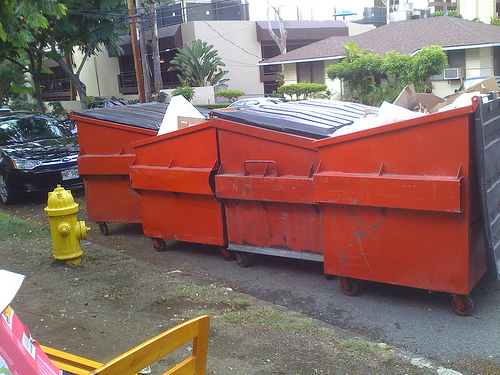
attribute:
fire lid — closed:
[58, 95, 166, 130]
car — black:
[2, 109, 90, 209]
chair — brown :
[30, 310, 237, 374]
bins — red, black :
[314, 93, 499, 315]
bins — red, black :
[211, 96, 383, 268]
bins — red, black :
[129, 121, 227, 251]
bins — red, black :
[72, 102, 228, 237]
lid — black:
[212, 77, 385, 157]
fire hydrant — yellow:
[37, 179, 97, 269]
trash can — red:
[310, 83, 493, 308]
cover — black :
[212, 86, 376, 138]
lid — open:
[475, 103, 498, 289]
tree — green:
[1, 0, 138, 111]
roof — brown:
[264, 17, 499, 63]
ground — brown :
[22, 265, 171, 365]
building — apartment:
[51, 12, 260, 102]